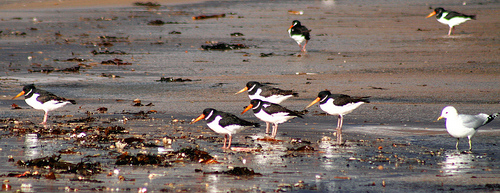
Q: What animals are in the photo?
A: Birds.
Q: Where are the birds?
A: Beach.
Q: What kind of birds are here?
A: Seabirds.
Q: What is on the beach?
A: Debris.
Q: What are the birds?
A: Black and white.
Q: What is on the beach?
A: Brown detritus on beach.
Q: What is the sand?
A: Brown.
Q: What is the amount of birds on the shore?
A: Seabirds.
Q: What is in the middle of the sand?
A: Four birds.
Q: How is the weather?
A: Sunny.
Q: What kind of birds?
A: Seagulls.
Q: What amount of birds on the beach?
A: 8.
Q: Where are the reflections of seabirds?
A: On the sand.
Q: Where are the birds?
A: On the beach.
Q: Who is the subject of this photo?
A: The birds.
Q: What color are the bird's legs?
A: Orange.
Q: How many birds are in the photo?
A: 8.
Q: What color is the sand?
A: Brown.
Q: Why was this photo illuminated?
A: Sunlight.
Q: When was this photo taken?
A: During the day.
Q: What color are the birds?
A: Black.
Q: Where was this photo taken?
A: The beach.